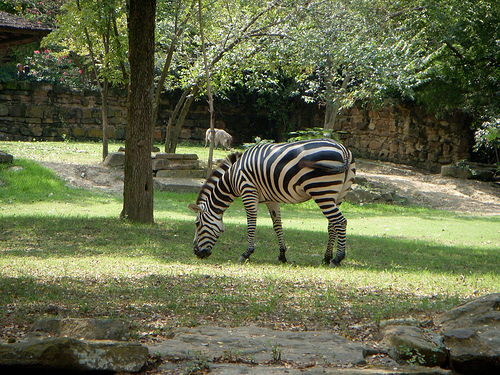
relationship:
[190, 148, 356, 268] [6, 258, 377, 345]
zebra on grass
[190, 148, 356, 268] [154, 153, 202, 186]
zebra in front of outcropping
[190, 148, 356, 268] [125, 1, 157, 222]
zebra to right of tree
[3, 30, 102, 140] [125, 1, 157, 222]
stone wall behind tree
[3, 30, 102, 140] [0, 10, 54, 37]
stone wall beneath roof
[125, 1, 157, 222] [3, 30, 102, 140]
tree in front of stone wall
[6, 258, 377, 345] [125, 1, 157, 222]
grass below tree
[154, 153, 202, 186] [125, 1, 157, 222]
outcropping behind tree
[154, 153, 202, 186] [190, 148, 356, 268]
outcropping to left of zebra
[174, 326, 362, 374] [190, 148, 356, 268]
rocks in front of zebra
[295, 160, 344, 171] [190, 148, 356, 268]
tail attached to zebra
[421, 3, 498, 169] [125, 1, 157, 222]
shrub to right of tree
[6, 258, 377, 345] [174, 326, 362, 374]
grass above rocks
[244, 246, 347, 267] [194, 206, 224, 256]
hooves next to head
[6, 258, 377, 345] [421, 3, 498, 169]
grass in front of shrub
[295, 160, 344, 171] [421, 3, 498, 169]
tail below shrub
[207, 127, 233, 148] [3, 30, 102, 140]
animal in front of stone wall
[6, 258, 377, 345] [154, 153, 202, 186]
grass surrounding outcropping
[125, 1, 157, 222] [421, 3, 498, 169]
tree in front of shrub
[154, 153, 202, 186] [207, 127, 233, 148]
outcropping in front of animal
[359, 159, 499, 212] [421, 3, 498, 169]
path in front of shrub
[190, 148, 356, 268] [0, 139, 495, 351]
zebra in foreground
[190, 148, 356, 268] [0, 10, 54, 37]
zebra below roof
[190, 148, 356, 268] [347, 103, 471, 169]
zebra to right of rock wall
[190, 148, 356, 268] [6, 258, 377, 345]
zebra munching on grass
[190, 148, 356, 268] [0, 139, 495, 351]
zebra standing in foreground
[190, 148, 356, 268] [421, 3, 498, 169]
zebra left of shrub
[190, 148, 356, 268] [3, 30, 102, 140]
zebra left of stone wall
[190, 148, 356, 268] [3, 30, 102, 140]
zebra below stone wall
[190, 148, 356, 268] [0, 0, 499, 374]
zebra in zoo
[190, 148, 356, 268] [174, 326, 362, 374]
zebra eating near rocks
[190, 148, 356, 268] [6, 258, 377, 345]
zebra looking at grass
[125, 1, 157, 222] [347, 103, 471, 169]
tree to left of rock wall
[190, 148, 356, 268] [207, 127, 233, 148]
zebra far from animal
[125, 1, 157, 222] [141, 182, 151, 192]
tree has hole